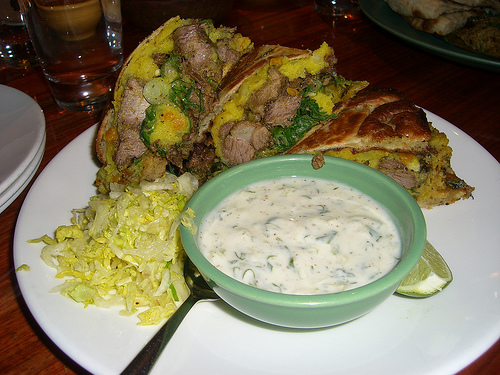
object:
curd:
[226, 179, 385, 280]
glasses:
[320, 0, 366, 33]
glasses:
[0, 0, 41, 72]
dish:
[11, 105, 499, 375]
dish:
[0, 81, 46, 218]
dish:
[357, 2, 500, 69]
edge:
[400, 187, 427, 273]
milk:
[255, 189, 368, 285]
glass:
[24, 0, 126, 114]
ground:
[0, 0, 500, 375]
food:
[36, 16, 474, 323]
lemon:
[394, 240, 454, 299]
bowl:
[178, 152, 428, 330]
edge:
[263, 291, 353, 309]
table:
[4, 0, 500, 375]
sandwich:
[91, 14, 476, 208]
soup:
[198, 172, 400, 294]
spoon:
[119, 257, 219, 375]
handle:
[119, 292, 201, 375]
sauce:
[191, 167, 404, 295]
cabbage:
[27, 174, 195, 325]